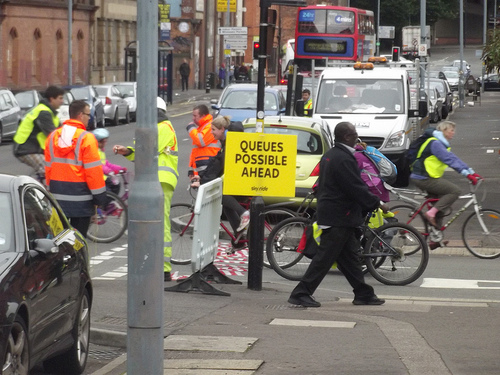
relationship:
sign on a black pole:
[222, 129, 297, 197] [248, 0, 273, 290]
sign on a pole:
[222, 129, 297, 197] [244, 10, 278, 72]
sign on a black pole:
[222, 129, 297, 197] [246, 15, 282, 292]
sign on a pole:
[222, 129, 297, 197] [247, 203, 264, 290]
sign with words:
[222, 129, 297, 197] [234, 139, 287, 191]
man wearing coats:
[46, 99, 105, 238] [51, 126, 231, 192]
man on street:
[288, 120, 384, 308] [0, 44, 496, 373]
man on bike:
[410, 119, 481, 234] [394, 190, 489, 249]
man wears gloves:
[410, 119, 481, 234] [465, 171, 479, 186]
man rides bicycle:
[410, 119, 475, 234] [384, 172, 498, 261]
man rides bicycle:
[288, 120, 384, 308] [268, 208, 430, 289]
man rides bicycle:
[180, 104, 227, 188] [78, 179, 140, 252]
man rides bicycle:
[46, 99, 105, 238] [160, 196, 305, 265]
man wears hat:
[5, 81, 77, 215] [39, 79, 77, 99]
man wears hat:
[146, 90, 182, 277] [143, 92, 171, 113]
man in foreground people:
[46, 99, 105, 238] [10, 80, 481, 309]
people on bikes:
[319, 118, 440, 237] [272, 209, 405, 284]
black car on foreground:
[1, 173, 94, 373] [0, 172, 498, 364]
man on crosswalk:
[46, 99, 105, 238] [375, 239, 497, 309]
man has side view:
[288, 120, 384, 308] [316, 116, 372, 296]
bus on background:
[294, 0, 374, 101] [5, 0, 497, 80]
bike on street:
[266, 196, 428, 286] [0, 105, 498, 298]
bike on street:
[381, 177, 498, 259] [0, 105, 498, 298]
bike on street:
[168, 181, 308, 268] [0, 105, 498, 298]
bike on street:
[34, 171, 128, 243] [0, 105, 498, 298]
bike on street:
[292, 190, 428, 256] [0, 105, 498, 298]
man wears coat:
[46, 99, 106, 246] [43, 125, 93, 200]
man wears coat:
[185, 104, 221, 183] [43, 125, 93, 200]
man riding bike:
[410, 119, 481, 234] [381, 177, 498, 259]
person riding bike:
[189, 117, 253, 253] [169, 173, 306, 269]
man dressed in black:
[288, 120, 384, 308] [287, 140, 384, 302]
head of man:
[333, 119, 362, 149] [284, 122, 386, 307]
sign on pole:
[222, 129, 297, 197] [244, 199, 263, 289]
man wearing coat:
[46, 99, 105, 238] [39, 116, 105, 191]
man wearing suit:
[296, 116, 407, 308] [296, 136, 381, 299]